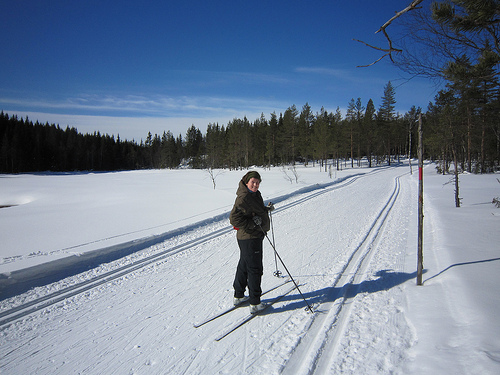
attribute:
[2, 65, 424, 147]
clouds — white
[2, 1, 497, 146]
sky — blue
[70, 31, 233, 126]
clouds — white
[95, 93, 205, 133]
clouds — white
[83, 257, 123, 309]
snow — white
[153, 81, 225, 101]
clouds — white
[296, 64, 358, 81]
cloud — white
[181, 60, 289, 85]
cloud — white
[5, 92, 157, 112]
cloud — white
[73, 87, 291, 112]
cloud — white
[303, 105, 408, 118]
cloud — white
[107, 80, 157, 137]
clouds — white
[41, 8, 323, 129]
sky — blue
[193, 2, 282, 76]
sky — blue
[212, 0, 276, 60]
clouds — white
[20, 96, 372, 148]
cloud — white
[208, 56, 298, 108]
clouds — white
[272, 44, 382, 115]
clouds — white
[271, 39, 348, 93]
clouds — in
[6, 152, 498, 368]
snow — white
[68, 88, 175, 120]
clouds — white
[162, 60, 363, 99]
clouds — white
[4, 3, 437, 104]
sky — blue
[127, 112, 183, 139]
clouds — white